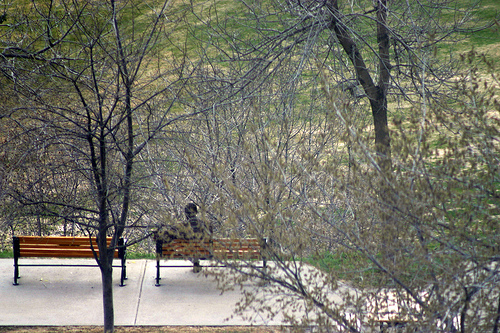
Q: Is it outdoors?
A: Yes, it is outdoors.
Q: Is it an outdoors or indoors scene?
A: It is outdoors.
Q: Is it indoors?
A: No, it is outdoors.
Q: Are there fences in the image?
A: No, there are no fences.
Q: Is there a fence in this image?
A: No, there are no fences.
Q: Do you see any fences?
A: No, there are no fences.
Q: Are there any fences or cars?
A: No, there are no fences or cars.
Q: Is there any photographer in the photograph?
A: No, there are no photographers.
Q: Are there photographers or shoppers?
A: No, there are no photographers or shoppers.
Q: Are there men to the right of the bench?
A: Yes, there is a man to the right of the bench.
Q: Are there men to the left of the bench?
A: No, the man is to the right of the bench.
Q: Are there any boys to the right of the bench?
A: No, there is a man to the right of the bench.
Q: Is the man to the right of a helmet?
A: No, the man is to the right of the bench.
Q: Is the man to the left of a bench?
A: No, the man is to the right of a bench.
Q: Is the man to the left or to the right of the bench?
A: The man is to the right of the bench.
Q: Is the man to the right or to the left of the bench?
A: The man is to the right of the bench.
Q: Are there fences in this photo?
A: No, there are no fences.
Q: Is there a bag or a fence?
A: No, there are no fences or bags.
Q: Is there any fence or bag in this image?
A: No, there are no fences or bags.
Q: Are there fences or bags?
A: No, there are no fences or bags.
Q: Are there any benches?
A: Yes, there is a bench.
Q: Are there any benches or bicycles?
A: Yes, there is a bench.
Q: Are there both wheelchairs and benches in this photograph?
A: No, there is a bench but no wheelchairs.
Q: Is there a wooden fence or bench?
A: Yes, there is a wood bench.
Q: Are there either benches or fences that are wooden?
A: Yes, the bench is wooden.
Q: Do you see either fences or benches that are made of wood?
A: Yes, the bench is made of wood.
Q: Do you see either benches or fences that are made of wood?
A: Yes, the bench is made of wood.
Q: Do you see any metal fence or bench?
A: Yes, there is a metal bench.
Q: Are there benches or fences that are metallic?
A: Yes, the bench is metallic.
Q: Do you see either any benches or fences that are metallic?
A: Yes, the bench is metallic.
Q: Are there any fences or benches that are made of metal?
A: Yes, the bench is made of metal.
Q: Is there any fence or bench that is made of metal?
A: Yes, the bench is made of metal.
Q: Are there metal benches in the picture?
A: Yes, there is a metal bench.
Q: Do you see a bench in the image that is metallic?
A: Yes, there is a bench that is metallic.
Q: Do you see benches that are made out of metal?
A: Yes, there is a bench that is made of metal.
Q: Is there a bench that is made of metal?
A: Yes, there is a bench that is made of metal.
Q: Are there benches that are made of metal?
A: Yes, there is a bench that is made of metal.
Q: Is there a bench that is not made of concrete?
A: Yes, there is a bench that is made of metal.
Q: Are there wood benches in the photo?
A: Yes, there is a wood bench.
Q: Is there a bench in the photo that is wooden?
A: Yes, there is a bench that is wooden.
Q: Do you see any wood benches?
A: Yes, there is a bench that is made of wood.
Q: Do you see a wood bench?
A: Yes, there is a bench that is made of wood.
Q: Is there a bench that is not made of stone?
A: Yes, there is a bench that is made of wood.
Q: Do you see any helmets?
A: No, there are no helmets.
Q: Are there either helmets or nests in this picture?
A: No, there are no helmets or nests.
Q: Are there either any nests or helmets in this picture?
A: No, there are no helmets or nests.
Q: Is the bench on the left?
A: Yes, the bench is on the left of the image.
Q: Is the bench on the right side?
A: No, the bench is on the left of the image.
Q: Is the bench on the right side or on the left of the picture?
A: The bench is on the left of the image.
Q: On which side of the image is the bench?
A: The bench is on the left of the image.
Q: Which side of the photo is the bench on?
A: The bench is on the left of the image.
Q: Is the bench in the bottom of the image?
A: Yes, the bench is in the bottom of the image.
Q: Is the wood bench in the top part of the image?
A: No, the bench is in the bottom of the image.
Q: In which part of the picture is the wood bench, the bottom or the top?
A: The bench is in the bottom of the image.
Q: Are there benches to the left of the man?
A: Yes, there is a bench to the left of the man.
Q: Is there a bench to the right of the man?
A: No, the bench is to the left of the man.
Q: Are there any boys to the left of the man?
A: No, there is a bench to the left of the man.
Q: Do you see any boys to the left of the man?
A: No, there is a bench to the left of the man.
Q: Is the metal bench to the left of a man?
A: Yes, the bench is to the left of a man.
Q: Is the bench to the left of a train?
A: No, the bench is to the left of a man.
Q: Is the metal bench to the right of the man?
A: No, the bench is to the left of the man.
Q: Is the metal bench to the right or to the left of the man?
A: The bench is to the left of the man.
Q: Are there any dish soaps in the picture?
A: No, there are no dish soaps.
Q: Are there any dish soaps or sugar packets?
A: No, there are no dish soaps or sugar packets.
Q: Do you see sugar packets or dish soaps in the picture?
A: No, there are no dish soaps or sugar packets.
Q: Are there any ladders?
A: No, there are no ladders.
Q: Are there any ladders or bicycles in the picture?
A: No, there are no ladders or bicycles.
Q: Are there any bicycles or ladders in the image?
A: No, there are no ladders or bicycles.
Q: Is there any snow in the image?
A: Yes, there is snow.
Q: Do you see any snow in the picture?
A: Yes, there is snow.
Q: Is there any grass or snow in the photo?
A: Yes, there is snow.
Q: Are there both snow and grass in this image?
A: Yes, there are both snow and grass.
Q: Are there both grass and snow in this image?
A: Yes, there are both snow and grass.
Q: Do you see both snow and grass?
A: Yes, there are both snow and grass.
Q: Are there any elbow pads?
A: No, there are no elbow pads.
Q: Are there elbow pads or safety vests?
A: No, there are no elbow pads or safety vests.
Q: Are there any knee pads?
A: No, there are no knee pads.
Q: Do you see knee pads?
A: No, there are no knee pads.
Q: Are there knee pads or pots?
A: No, there are no knee pads or pots.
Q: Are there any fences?
A: No, there are no fences.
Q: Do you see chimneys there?
A: No, there are no chimneys.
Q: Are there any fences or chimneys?
A: No, there are no chimneys or fences.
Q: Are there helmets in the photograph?
A: No, there are no helmets.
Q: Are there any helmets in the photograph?
A: No, there are no helmets.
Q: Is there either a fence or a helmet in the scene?
A: No, there are no helmets or fences.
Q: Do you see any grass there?
A: Yes, there is grass.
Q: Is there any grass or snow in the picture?
A: Yes, there is grass.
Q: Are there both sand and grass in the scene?
A: No, there is grass but no sand.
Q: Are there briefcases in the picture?
A: No, there are no briefcases.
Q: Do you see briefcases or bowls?
A: No, there are no briefcases or bowls.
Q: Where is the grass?
A: The grass is on the hill.